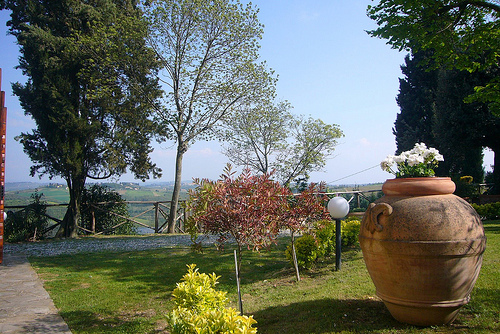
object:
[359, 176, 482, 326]
planter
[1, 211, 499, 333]
ground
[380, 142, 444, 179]
flowers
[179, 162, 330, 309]
tree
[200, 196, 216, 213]
red leaves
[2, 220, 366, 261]
wall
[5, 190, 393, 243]
wood fence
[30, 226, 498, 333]
lawn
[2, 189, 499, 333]
garden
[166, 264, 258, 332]
yellow leaves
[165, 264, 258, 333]
bush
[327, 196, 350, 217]
globe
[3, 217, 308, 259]
gravel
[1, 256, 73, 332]
concrete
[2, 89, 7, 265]
bricks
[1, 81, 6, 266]
building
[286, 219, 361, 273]
bush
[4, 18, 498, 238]
overlook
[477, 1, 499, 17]
green leaves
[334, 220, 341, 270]
lightpole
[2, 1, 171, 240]
tree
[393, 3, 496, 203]
tree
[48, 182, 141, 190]
homes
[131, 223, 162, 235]
water